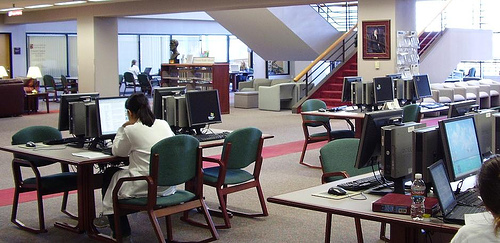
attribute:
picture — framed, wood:
[359, 18, 399, 63]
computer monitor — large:
[436, 112, 485, 183]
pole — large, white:
[76, 15, 123, 100]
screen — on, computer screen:
[446, 109, 492, 176]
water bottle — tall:
[408, 172, 425, 221]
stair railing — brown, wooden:
[296, 20, 354, 112]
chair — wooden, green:
[204, 128, 282, 239]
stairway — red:
[308, 45, 366, 110]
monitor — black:
[380, 120, 424, 180]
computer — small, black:
[420, 159, 493, 228]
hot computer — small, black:
[393, 104, 498, 204]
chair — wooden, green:
[282, 102, 350, 173]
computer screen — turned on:
[441, 114, 485, 181]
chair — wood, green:
[207, 130, 282, 229]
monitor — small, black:
[440, 119, 483, 178]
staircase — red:
[306, 62, 353, 110]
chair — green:
[10, 125, 82, 240]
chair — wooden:
[113, 136, 210, 241]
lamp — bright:
[20, 52, 57, 92]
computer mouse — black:
[321, 177, 356, 204]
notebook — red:
[374, 192, 441, 214]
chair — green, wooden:
[312, 129, 419, 199]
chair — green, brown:
[204, 126, 267, 229]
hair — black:
[125, 92, 155, 127]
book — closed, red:
[366, 187, 438, 214]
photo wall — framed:
[357, 22, 395, 63]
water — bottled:
[408, 171, 428, 220]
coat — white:
[97, 113, 190, 213]